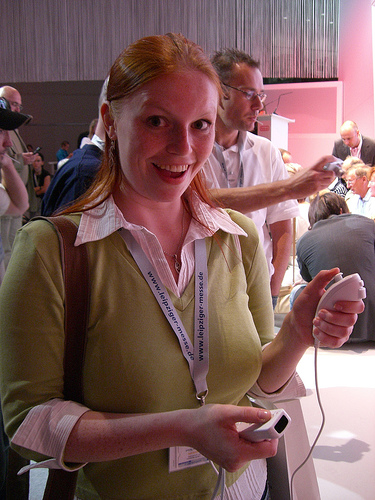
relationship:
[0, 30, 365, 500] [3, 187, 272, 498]
people wearing sweater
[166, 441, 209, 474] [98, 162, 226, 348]
name badge around neck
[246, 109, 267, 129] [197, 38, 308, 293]
toothpick in man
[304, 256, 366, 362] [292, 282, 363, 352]
controller in hand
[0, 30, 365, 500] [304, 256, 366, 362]
people has controller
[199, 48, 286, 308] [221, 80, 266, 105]
man wearing glasses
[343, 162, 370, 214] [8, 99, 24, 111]
man wearing glasses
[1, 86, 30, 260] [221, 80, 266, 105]
man wearing glasses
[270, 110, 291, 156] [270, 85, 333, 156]
white podium against wall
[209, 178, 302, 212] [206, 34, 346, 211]
arm of man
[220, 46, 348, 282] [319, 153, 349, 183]
man holding camera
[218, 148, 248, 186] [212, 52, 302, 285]
gray lanyard on man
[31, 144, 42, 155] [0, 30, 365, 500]
cellphone on people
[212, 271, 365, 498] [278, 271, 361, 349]
wii nunchuck i hand in hand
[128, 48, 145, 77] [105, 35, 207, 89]
hair of woman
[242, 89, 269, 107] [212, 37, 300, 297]
glasses on man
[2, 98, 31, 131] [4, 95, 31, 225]
cap on man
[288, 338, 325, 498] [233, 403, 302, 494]
cord with remote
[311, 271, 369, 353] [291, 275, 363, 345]
controller in hand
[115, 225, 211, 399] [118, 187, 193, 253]
gray lanyard around neck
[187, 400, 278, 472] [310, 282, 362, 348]
woman hand holding controller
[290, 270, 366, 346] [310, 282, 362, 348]
woman hand holding controller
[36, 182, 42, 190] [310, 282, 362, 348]
woman hand holding controller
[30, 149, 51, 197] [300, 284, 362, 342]
man holding controller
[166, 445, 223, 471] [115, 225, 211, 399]
name badge on gray lanyard